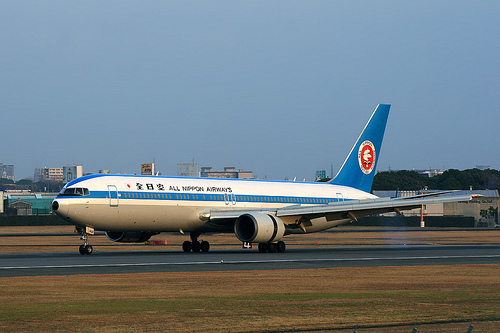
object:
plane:
[49, 102, 472, 256]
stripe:
[88, 190, 359, 205]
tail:
[329, 103, 393, 193]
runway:
[0, 244, 500, 276]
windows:
[124, 193, 127, 198]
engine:
[232, 211, 288, 252]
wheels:
[84, 244, 92, 255]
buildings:
[40, 166, 63, 184]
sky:
[1, 0, 498, 183]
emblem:
[357, 138, 376, 175]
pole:
[419, 192, 425, 227]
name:
[135, 182, 233, 193]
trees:
[445, 180, 450, 186]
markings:
[0, 265, 13, 270]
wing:
[198, 189, 485, 244]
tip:
[51, 197, 71, 218]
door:
[107, 185, 119, 207]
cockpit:
[51, 173, 121, 232]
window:
[62, 187, 90, 196]